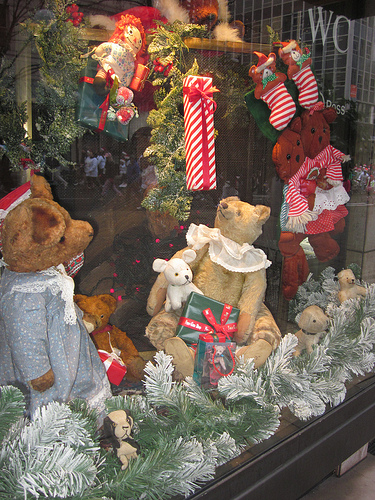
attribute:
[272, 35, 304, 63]
head — teddy bear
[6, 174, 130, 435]
teddy bear — large, brown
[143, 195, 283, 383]
teddy bear — large, tan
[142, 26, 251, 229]
christmas garland — green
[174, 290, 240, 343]
package — green, red, wrapped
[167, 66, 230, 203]
gift — tall, red, white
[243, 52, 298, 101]
bear — teddy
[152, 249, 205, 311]
dog — white, plush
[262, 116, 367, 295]
bears — dark brown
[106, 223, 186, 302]
christmas lights — red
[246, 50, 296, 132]
stocking — teddy bear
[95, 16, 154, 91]
doll — Raggedy Anne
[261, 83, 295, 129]
stocking — striped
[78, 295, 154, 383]
teddy bear — brown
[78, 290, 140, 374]
bear — plush, teddy bear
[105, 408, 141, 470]
black dog — tan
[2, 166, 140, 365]
bear — teddy bear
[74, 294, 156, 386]
teddy bear — brown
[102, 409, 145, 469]
dog doll — plush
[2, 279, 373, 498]
green/christmas garland — green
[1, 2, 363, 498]
window — store front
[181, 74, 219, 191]
present — red, white, wrapped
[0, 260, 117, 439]
outfit — blue, white